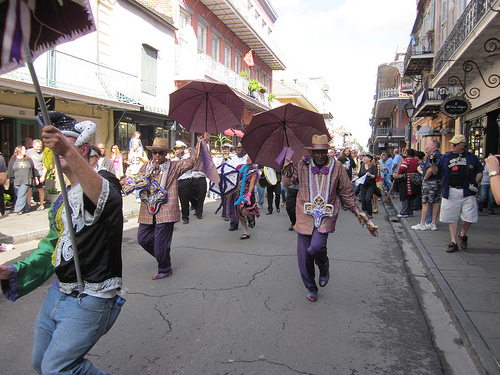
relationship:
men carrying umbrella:
[274, 131, 381, 304] [234, 103, 331, 174]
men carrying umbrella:
[167, 137, 213, 226] [166, 79, 246, 151]